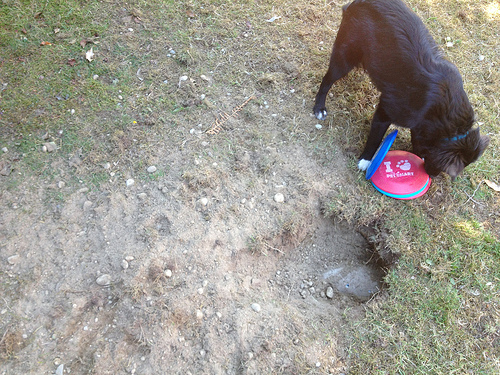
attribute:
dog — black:
[325, 3, 487, 187]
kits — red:
[383, 136, 418, 201]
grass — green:
[6, 14, 42, 46]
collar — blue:
[445, 128, 467, 142]